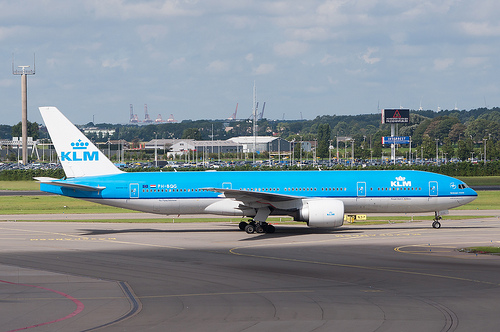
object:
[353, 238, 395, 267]
floor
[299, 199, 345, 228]
engine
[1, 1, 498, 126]
clouds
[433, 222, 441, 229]
landing gear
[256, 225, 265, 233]
landing gear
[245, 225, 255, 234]
landing gear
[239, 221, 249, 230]
landing gear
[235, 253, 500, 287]
line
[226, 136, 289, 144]
roof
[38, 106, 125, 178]
tail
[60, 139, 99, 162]
logo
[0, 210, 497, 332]
ground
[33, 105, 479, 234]
airplane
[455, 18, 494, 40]
clouds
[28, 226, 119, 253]
lines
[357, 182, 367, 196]
door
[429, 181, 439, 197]
door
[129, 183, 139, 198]
door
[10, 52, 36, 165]
tower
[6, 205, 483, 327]
runway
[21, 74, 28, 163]
pole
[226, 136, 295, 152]
building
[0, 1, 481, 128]
sky